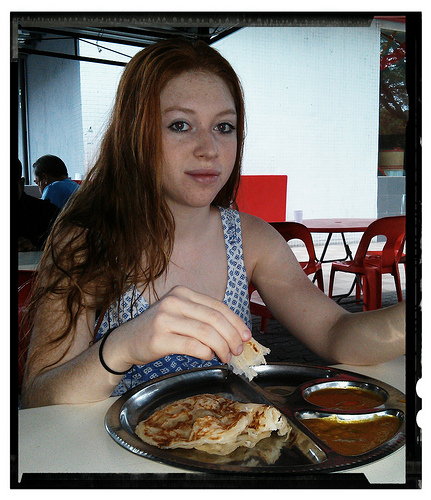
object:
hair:
[17, 38, 248, 393]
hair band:
[98, 328, 135, 375]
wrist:
[84, 320, 128, 399]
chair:
[328, 215, 405, 313]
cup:
[294, 210, 303, 224]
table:
[301, 218, 378, 229]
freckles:
[164, 134, 193, 152]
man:
[32, 154, 81, 209]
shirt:
[40, 177, 81, 206]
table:
[19, 354, 406, 489]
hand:
[129, 284, 252, 365]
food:
[227, 337, 270, 384]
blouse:
[91, 205, 251, 397]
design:
[232, 298, 238, 306]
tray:
[103, 360, 406, 475]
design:
[237, 280, 244, 287]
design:
[235, 309, 241, 316]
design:
[122, 312, 129, 320]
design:
[234, 227, 241, 234]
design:
[234, 269, 240, 276]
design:
[219, 207, 224, 212]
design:
[102, 321, 108, 328]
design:
[125, 295, 132, 303]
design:
[221, 214, 226, 220]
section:
[120, 369, 327, 469]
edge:
[105, 402, 120, 444]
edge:
[308, 227, 367, 233]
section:
[249, 365, 328, 396]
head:
[114, 38, 238, 209]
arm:
[20, 237, 124, 410]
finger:
[171, 332, 215, 361]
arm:
[252, 219, 406, 367]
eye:
[167, 119, 193, 133]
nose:
[193, 130, 219, 160]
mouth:
[183, 167, 221, 185]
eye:
[213, 122, 235, 135]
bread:
[134, 393, 289, 456]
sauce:
[301, 414, 401, 458]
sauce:
[307, 387, 386, 410]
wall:
[20, 36, 407, 407]